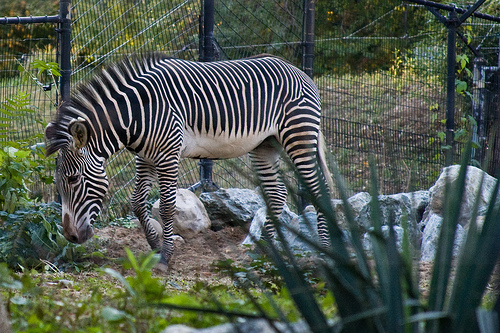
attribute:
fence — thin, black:
[315, 51, 490, 191]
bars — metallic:
[2, 5, 498, 178]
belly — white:
[178, 129, 275, 159]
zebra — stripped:
[41, 49, 341, 245]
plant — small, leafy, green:
[8, 209, 53, 263]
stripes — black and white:
[156, 63, 276, 120]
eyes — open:
[47, 164, 98, 201]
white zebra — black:
[55, 47, 369, 203]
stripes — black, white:
[23, 63, 348, 262]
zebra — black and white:
[35, 58, 327, 253]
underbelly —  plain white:
[182, 135, 277, 169]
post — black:
[197, 0, 214, 190]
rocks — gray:
[148, 161, 498, 263]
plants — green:
[111, 246, 173, 311]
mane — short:
[52, 44, 168, 124]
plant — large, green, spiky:
[148, 129, 495, 331]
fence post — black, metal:
[58, 3, 69, 210]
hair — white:
[286, 140, 341, 201]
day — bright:
[276, 70, 426, 125]